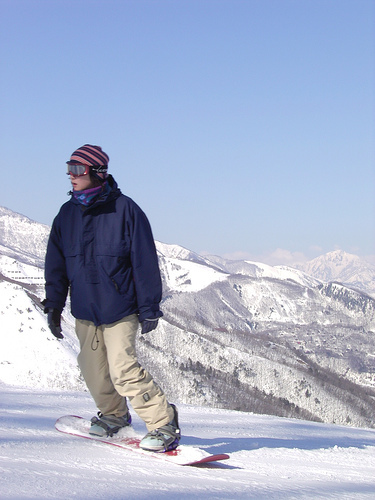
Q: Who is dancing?
A: No one.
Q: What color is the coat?
A: Blue.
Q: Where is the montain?
A: Background.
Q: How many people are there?
A: One.